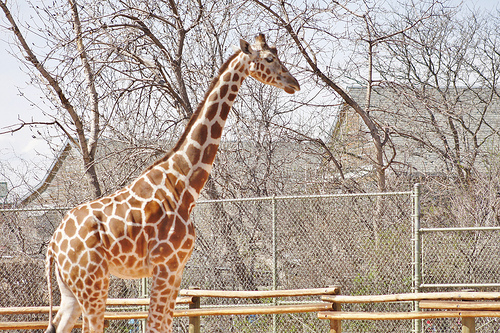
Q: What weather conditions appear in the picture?
A: It is clear.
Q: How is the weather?
A: It is clear.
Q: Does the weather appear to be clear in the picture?
A: Yes, it is clear.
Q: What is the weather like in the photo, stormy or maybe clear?
A: It is clear.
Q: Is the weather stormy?
A: No, it is clear.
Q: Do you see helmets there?
A: No, there are no helmets.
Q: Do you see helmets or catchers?
A: No, there are no helmets or catchers.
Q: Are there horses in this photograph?
A: No, there are no horses.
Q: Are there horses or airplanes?
A: No, there are no horses or airplanes.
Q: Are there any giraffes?
A: Yes, there is a giraffe.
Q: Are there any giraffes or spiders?
A: Yes, there is a giraffe.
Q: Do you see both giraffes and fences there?
A: Yes, there are both a giraffe and a fence.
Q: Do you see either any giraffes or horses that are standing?
A: Yes, the giraffe is standing.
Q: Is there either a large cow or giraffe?
A: Yes, there is a large giraffe.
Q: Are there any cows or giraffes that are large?
A: Yes, the giraffe is large.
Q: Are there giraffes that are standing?
A: Yes, there is a giraffe that is standing.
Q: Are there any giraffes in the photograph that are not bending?
A: Yes, there is a giraffe that is standing.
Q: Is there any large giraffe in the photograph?
A: Yes, there is a large giraffe.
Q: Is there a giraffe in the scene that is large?
A: Yes, there is a giraffe that is large.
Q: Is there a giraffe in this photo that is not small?
A: Yes, there is a large giraffe.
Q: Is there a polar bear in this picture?
A: No, there are no polar bears.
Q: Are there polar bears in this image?
A: No, there are no polar bears.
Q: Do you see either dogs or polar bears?
A: No, there are no polar bears or dogs.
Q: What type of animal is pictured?
A: The animal is a giraffe.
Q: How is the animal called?
A: The animal is a giraffe.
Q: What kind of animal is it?
A: The animal is a giraffe.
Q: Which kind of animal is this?
A: This is a giraffe.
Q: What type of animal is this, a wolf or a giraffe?
A: This is a giraffe.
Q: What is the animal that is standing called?
A: The animal is a giraffe.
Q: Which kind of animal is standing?
A: The animal is a giraffe.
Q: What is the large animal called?
A: The animal is a giraffe.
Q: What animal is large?
A: The animal is a giraffe.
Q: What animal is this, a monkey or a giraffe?
A: This is a giraffe.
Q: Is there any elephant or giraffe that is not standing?
A: No, there is a giraffe but it is standing.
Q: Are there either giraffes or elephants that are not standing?
A: No, there is a giraffe but it is standing.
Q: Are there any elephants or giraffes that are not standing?
A: No, there is a giraffe but it is standing.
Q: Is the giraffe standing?
A: Yes, the giraffe is standing.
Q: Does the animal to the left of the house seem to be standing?
A: Yes, the giraffe is standing.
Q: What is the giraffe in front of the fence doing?
A: The giraffe is standing.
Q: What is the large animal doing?
A: The giraffe is standing.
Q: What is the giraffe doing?
A: The giraffe is standing.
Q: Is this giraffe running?
A: No, the giraffe is standing.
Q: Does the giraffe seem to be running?
A: No, the giraffe is standing.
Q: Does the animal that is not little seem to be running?
A: No, the giraffe is standing.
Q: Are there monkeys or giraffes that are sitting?
A: No, there is a giraffe but it is standing.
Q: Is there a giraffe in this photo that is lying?
A: No, there is a giraffe but it is standing.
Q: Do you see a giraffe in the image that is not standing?
A: No, there is a giraffe but it is standing.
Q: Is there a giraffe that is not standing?
A: No, there is a giraffe but it is standing.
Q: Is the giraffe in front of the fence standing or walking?
A: The giraffe is standing.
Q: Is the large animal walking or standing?
A: The giraffe is standing.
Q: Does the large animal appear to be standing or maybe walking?
A: The giraffe is standing.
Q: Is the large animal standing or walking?
A: The giraffe is standing.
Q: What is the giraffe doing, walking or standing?
A: The giraffe is standing.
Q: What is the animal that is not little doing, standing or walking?
A: The giraffe is standing.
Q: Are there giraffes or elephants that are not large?
A: No, there is a giraffe but it is large.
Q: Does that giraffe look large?
A: Yes, the giraffe is large.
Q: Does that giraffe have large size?
A: Yes, the giraffe is large.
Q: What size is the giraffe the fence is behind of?
A: The giraffe is large.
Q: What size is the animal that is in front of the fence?
A: The giraffe is large.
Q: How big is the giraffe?
A: The giraffe is large.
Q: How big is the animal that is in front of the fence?
A: The giraffe is large.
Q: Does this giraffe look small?
A: No, the giraffe is large.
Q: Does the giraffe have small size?
A: No, the giraffe is large.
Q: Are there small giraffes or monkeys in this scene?
A: No, there is a giraffe but it is large.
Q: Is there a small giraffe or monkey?
A: No, there is a giraffe but it is large.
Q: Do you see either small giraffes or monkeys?
A: No, there is a giraffe but it is large.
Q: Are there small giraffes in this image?
A: No, there is a giraffe but it is large.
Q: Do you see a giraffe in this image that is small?
A: No, there is a giraffe but it is large.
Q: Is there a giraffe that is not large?
A: No, there is a giraffe but it is large.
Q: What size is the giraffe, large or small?
A: The giraffe is large.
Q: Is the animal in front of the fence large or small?
A: The giraffe is large.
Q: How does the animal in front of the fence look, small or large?
A: The giraffe is large.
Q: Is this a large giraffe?
A: Yes, this is a large giraffe.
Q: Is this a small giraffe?
A: No, this is a large giraffe.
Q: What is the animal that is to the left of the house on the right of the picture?
A: The animal is a giraffe.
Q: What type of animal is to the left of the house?
A: The animal is a giraffe.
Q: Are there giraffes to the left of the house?
A: Yes, there is a giraffe to the left of the house.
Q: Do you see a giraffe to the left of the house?
A: Yes, there is a giraffe to the left of the house.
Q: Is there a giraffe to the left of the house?
A: Yes, there is a giraffe to the left of the house.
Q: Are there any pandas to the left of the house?
A: No, there is a giraffe to the left of the house.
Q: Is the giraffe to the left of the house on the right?
A: Yes, the giraffe is to the left of the house.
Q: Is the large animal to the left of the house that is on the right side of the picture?
A: Yes, the giraffe is to the left of the house.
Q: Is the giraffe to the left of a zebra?
A: No, the giraffe is to the left of the house.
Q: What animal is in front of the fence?
A: The giraffe is in front of the fence.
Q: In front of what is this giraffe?
A: The giraffe is in front of the fence.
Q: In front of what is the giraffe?
A: The giraffe is in front of the fence.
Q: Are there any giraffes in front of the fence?
A: Yes, there is a giraffe in front of the fence.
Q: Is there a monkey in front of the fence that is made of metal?
A: No, there is a giraffe in front of the fence.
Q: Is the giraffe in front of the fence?
A: Yes, the giraffe is in front of the fence.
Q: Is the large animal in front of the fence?
A: Yes, the giraffe is in front of the fence.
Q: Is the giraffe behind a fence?
A: No, the giraffe is in front of a fence.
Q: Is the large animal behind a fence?
A: No, the giraffe is in front of a fence.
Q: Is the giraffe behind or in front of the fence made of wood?
A: The giraffe is in front of the fence.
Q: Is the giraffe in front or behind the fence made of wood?
A: The giraffe is in front of the fence.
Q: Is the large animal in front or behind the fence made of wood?
A: The giraffe is in front of the fence.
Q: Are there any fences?
A: Yes, there is a fence.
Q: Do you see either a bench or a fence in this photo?
A: Yes, there is a fence.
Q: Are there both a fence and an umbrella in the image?
A: No, there is a fence but no umbrellas.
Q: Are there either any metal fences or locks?
A: Yes, there is a metal fence.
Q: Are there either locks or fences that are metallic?
A: Yes, the fence is metallic.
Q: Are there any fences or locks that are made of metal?
A: Yes, the fence is made of metal.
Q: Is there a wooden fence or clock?
A: Yes, there is a wood fence.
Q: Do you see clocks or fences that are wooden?
A: Yes, the fence is wooden.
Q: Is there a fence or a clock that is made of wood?
A: Yes, the fence is made of wood.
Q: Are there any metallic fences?
A: Yes, there is a metal fence.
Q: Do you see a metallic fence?
A: Yes, there is a metal fence.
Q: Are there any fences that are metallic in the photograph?
A: Yes, there is a metal fence.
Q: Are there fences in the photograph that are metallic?
A: Yes, there is a fence that is metallic.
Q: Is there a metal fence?
A: Yes, there is a fence that is made of metal.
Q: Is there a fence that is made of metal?
A: Yes, there is a fence that is made of metal.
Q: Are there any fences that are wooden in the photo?
A: Yes, there is a wood fence.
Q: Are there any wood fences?
A: Yes, there is a wood fence.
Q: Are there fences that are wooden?
A: Yes, there is a fence that is wooden.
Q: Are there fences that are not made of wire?
A: Yes, there is a fence that is made of wood.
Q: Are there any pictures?
A: No, there are no pictures.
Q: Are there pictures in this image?
A: No, there are no pictures.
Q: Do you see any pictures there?
A: No, there are no pictures.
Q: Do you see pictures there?
A: No, there are no pictures.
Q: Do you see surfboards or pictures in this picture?
A: No, there are no pictures or surfboards.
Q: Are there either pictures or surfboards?
A: No, there are no pictures or surfboards.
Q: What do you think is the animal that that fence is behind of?
A: The animal is a giraffe.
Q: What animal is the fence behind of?
A: The fence is behind the giraffe.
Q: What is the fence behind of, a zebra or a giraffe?
A: The fence is behind a giraffe.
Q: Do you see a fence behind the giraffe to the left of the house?
A: Yes, there is a fence behind the giraffe.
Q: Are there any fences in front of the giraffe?
A: No, the fence is behind the giraffe.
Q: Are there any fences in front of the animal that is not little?
A: No, the fence is behind the giraffe.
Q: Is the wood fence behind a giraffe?
A: Yes, the fence is behind a giraffe.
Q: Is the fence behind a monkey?
A: No, the fence is behind a giraffe.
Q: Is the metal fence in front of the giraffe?
A: No, the fence is behind the giraffe.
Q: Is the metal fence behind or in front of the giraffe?
A: The fence is behind the giraffe.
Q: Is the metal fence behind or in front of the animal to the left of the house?
A: The fence is behind the giraffe.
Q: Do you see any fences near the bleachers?
A: Yes, there is a fence near the bleachers.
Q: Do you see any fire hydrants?
A: No, there are no fire hydrants.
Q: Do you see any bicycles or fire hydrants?
A: No, there are no fire hydrants or bicycles.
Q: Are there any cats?
A: No, there are no cats.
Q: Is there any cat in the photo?
A: No, there are no cats.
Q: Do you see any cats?
A: No, there are no cats.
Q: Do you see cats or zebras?
A: No, there are no cats or zebras.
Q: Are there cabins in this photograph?
A: No, there are no cabins.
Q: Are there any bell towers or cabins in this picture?
A: No, there are no cabins or bell towers.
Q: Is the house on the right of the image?
A: Yes, the house is on the right of the image.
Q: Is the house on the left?
A: No, the house is on the right of the image.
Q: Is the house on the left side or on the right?
A: The house is on the right of the image.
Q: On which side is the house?
A: The house is on the right of the image.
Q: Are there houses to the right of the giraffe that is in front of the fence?
A: Yes, there is a house to the right of the giraffe.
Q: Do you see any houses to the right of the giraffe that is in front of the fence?
A: Yes, there is a house to the right of the giraffe.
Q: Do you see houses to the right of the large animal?
A: Yes, there is a house to the right of the giraffe.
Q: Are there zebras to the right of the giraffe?
A: No, there is a house to the right of the giraffe.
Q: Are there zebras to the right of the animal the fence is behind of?
A: No, there is a house to the right of the giraffe.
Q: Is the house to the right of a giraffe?
A: Yes, the house is to the right of a giraffe.